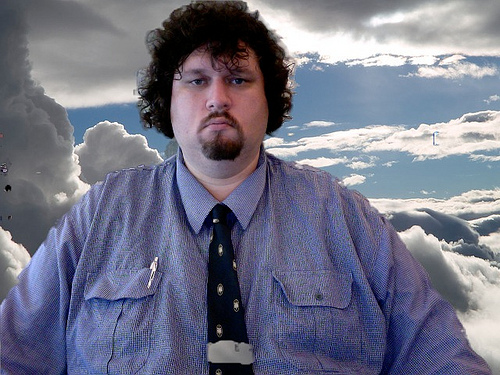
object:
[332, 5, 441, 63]
cloud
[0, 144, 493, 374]
shirt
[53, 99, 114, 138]
sky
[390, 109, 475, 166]
clouds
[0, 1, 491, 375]
man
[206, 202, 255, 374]
tie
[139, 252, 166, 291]
pen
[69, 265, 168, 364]
pocket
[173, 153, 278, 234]
collar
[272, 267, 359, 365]
pocket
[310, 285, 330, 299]
button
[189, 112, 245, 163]
goatee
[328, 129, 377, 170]
clouds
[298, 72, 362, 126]
sky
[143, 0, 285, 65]
hair